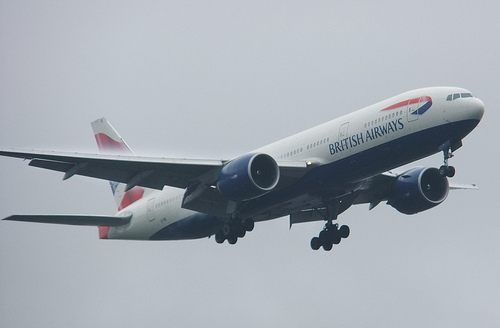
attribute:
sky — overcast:
[0, 0, 498, 325]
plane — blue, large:
[0, 85, 484, 250]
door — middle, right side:
[316, 112, 369, 146]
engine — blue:
[389, 163, 451, 214]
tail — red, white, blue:
[83, 113, 157, 210]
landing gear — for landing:
[440, 133, 461, 185]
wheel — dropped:
[220, 222, 235, 237]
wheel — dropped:
[226, 230, 238, 244]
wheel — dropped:
[309, 235, 322, 250]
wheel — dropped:
[338, 223, 350, 238]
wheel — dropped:
[329, 231, 342, 245]